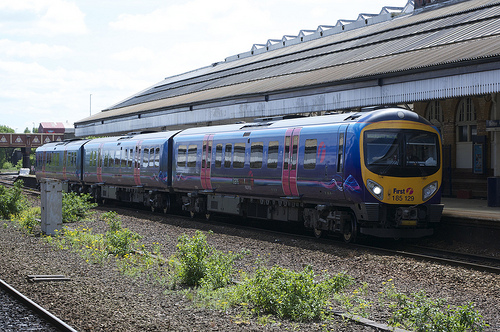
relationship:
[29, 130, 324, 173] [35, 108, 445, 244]
windows on train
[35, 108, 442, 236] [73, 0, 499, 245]
train at station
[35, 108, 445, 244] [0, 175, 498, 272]
train on track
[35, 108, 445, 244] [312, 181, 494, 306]
train on train tracks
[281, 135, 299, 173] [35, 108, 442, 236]
window on train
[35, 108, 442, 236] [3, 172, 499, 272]
train on tracks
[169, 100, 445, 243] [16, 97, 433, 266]
car of train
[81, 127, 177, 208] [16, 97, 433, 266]
car of train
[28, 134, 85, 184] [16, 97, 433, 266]
car of train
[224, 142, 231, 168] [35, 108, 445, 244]
window of train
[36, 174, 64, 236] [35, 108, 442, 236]
box on train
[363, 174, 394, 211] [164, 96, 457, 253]
headlight on train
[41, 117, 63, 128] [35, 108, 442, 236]
rooftop behind train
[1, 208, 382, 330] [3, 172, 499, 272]
gravel by tracks